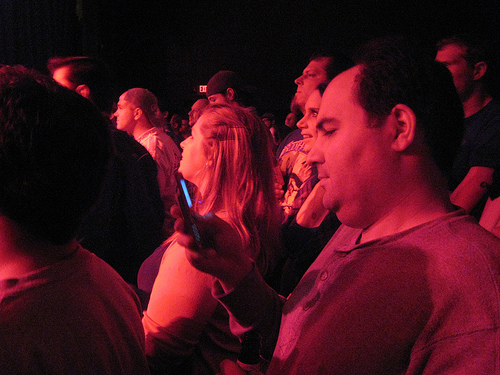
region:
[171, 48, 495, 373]
a man looking at his phone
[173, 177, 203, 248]
a cell phone turned on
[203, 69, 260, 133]
a man with a backwards ball cap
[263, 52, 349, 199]
a man with facial hair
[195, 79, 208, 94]
a distant exit sign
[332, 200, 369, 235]
a man's double chin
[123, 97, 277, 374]
a woman with blonde hair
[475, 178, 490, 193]
a tattoo on a man's left arm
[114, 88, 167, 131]
a backwards baseball cap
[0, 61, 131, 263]
the back of a person's head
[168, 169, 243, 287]
This is a cell phone.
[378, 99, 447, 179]
This is an ear.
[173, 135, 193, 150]
This is a nose.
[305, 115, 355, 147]
This is an eye.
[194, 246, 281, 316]
This is a wrist.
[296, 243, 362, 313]
This is a button.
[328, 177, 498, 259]
This is a man's neck.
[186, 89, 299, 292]
This is a woman's hair.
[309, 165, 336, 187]
This is a mouth.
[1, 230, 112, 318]
This is a shirt collar.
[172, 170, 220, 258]
the phone is on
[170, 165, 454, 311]
the man is holding a phone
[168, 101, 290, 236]
girl is looking up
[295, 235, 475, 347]
man is wearing a shirt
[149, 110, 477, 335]
the man is texting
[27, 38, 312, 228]
people are looking up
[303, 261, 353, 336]
the shirt has buttons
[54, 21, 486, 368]
the lights are red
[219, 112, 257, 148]
the hair is pinned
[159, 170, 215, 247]
the phone is red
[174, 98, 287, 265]
a woman with long hair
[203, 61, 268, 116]
a man with a black hat on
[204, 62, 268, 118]
man wearing his hat backwards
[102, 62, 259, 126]
two men with there hats to the back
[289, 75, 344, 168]
a woman smiling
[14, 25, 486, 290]
a group of people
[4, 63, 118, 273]
back of a mans head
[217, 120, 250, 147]
two bobby pins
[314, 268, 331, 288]
a button on a shirt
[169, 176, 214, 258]
Cell phone held by man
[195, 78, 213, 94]
Exit sign for the building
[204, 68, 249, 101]
Hat a man is wearing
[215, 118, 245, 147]
Bobby pins in the woman's hair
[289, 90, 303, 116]
Goatee on the man's face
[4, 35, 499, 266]
Group of people at the event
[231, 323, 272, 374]
Neck of the beer bottle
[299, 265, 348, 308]
Button on the front of the man's shirt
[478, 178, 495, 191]
Tattoo on the man's arm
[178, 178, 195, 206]
Screen of the cell phone